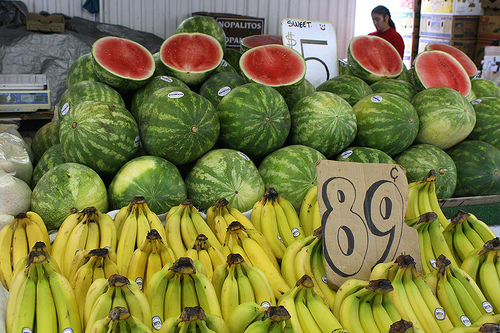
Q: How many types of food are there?
A: 2.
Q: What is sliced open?
A: Watermelon.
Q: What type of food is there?
A: Bananas and watermelon.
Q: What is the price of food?
A: $0.89.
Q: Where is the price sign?
A: On bananas.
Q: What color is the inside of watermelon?
A: Red.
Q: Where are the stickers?
A: On fruits.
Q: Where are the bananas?
A: Under watermelon.